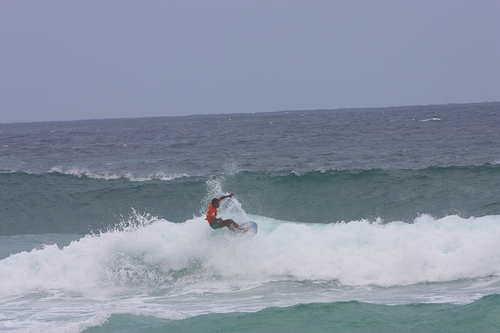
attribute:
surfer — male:
[204, 188, 238, 238]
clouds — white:
[390, 38, 460, 92]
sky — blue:
[347, 16, 487, 97]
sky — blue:
[21, 13, 411, 73]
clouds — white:
[19, 15, 430, 85]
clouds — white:
[235, 9, 325, 95]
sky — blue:
[37, 16, 496, 80]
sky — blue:
[77, 23, 495, 77]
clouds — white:
[128, 21, 337, 92]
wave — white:
[12, 232, 161, 316]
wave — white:
[77, 232, 173, 271]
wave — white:
[116, 233, 182, 292]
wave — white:
[146, 230, 205, 272]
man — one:
[194, 193, 243, 233]